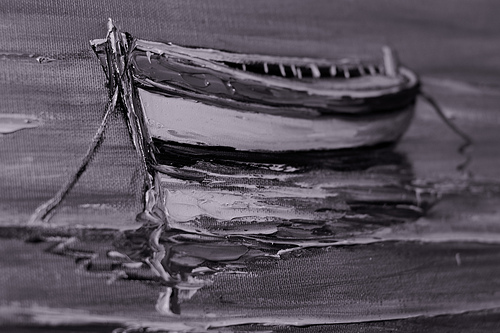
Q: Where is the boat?
A: In the water.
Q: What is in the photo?
A: Row boat.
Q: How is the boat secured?
A: Tied to two ropes.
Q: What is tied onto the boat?
A: Rope.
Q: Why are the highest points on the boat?
A: The two ends.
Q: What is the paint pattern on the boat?
A: Stripe.